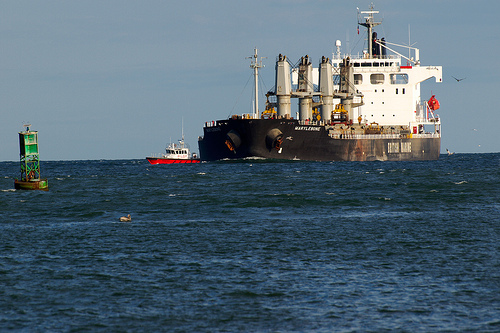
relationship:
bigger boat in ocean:
[197, 3, 441, 163] [49, 165, 453, 331]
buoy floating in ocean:
[14, 124, 49, 191] [0, 153, 499, 331]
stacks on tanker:
[336, 55, 360, 126] [191, 5, 446, 166]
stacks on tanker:
[316, 52, 336, 126] [191, 5, 446, 166]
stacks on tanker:
[291, 52, 318, 124] [191, 5, 446, 166]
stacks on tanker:
[273, 50, 294, 120] [191, 5, 446, 166]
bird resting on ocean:
[115, 209, 135, 229] [108, 195, 418, 284]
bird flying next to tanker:
[450, 71, 470, 89] [191, 5, 446, 166]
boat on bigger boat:
[146, 117, 202, 165] [191, 3, 454, 167]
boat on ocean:
[146, 117, 202, 165] [172, 258, 287, 330]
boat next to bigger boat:
[146, 117, 202, 165] [197, 3, 441, 163]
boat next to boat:
[139, 115, 219, 201] [196, 35, 439, 163]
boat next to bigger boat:
[146, 117, 202, 165] [191, 3, 454, 167]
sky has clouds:
[0, 0, 500, 153] [109, 29, 238, 69]